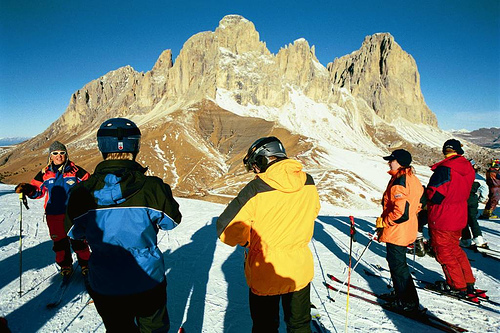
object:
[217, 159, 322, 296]
jacket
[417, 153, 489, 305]
outfit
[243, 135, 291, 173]
helmet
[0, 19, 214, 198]
mountain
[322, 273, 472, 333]
skis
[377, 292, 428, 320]
feet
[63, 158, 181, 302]
jacket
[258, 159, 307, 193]
hood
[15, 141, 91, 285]
woman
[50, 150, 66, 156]
sunglasses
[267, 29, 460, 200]
mountain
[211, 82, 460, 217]
snow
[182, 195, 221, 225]
snow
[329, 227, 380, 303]
ski pole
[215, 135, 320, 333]
skier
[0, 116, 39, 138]
clouds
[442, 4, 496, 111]
sky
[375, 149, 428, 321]
skier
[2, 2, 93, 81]
sky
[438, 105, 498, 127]
clouds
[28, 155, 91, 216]
coat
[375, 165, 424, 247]
coat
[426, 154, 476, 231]
coat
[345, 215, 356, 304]
pole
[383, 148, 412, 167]
hat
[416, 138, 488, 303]
man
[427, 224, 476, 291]
pants